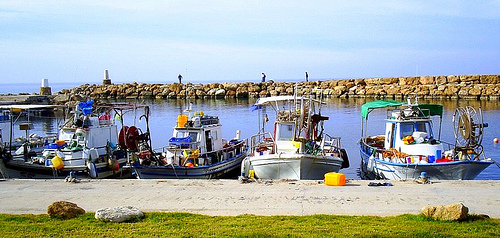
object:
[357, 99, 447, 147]
canopy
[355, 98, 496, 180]
boat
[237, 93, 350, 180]
boat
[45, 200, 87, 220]
rock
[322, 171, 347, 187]
jug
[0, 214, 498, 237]
grass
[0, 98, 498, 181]
water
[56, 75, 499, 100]
rock wall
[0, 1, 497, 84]
sky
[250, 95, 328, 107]
roof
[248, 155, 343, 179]
bow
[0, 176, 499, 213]
sand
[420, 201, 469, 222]
rock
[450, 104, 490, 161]
fan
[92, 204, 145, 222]
rock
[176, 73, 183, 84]
person